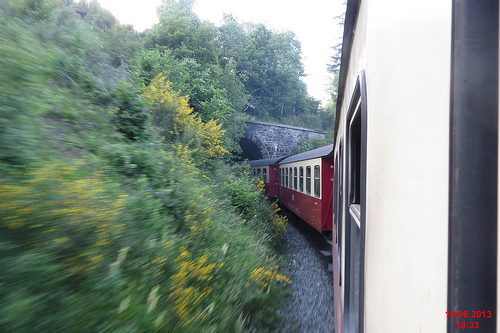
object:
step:
[319, 250, 332, 257]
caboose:
[329, 0, 500, 333]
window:
[346, 101, 363, 225]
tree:
[266, 34, 290, 74]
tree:
[263, 74, 288, 121]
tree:
[219, 23, 251, 80]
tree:
[217, 60, 249, 109]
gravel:
[312, 273, 314, 274]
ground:
[274, 221, 336, 332]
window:
[262, 168, 266, 182]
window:
[298, 166, 303, 192]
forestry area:
[0, 0, 311, 333]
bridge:
[241, 119, 328, 160]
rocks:
[272, 324, 280, 331]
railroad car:
[233, 154, 293, 198]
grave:
[240, 121, 323, 166]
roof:
[277, 144, 334, 165]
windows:
[294, 167, 298, 191]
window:
[314, 165, 321, 196]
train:
[239, 0, 500, 332]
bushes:
[0, 240, 45, 333]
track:
[286, 212, 343, 332]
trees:
[17, 153, 59, 326]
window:
[305, 165, 311, 195]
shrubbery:
[145, 209, 183, 333]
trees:
[156, 4, 176, 153]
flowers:
[215, 136, 217, 137]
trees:
[135, 0, 176, 180]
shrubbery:
[154, 7, 179, 159]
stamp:
[444, 309, 493, 330]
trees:
[184, 19, 215, 149]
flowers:
[156, 94, 157, 95]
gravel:
[332, 331, 333, 332]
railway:
[282, 216, 336, 333]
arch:
[230, 132, 270, 163]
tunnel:
[226, 131, 269, 164]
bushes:
[0, 0, 46, 55]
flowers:
[180, 316, 183, 319]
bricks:
[265, 141, 274, 144]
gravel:
[295, 306, 298, 308]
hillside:
[0, 0, 295, 333]